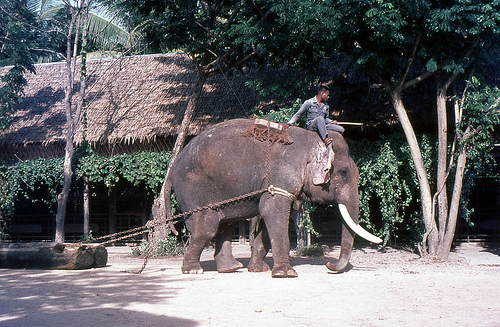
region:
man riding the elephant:
[213, 55, 407, 293]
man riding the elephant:
[247, 68, 372, 234]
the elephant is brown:
[157, 94, 369, 287]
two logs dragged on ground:
[0, 242, 107, 269]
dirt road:
[1, 255, 499, 324]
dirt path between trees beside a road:
[455, 235, 497, 264]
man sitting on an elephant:
[285, 86, 345, 143]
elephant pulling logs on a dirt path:
[0, 118, 382, 269]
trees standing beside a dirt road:
[52, 0, 97, 245]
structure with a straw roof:
[0, 48, 256, 241]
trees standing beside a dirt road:
[115, 0, 499, 261]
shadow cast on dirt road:
[1, 268, 214, 324]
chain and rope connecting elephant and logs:
[66, 185, 294, 248]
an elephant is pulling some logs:
[2, 81, 384, 280]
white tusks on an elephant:
[336, 200, 384, 245]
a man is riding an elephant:
[160, 75, 382, 275]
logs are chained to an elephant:
[6, 109, 387, 281]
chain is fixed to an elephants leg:
[161, 177, 308, 230]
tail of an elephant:
[161, 168, 180, 236]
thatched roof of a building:
[1, 52, 411, 152]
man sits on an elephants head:
[287, 80, 389, 275]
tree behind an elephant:
[160, 0, 499, 280]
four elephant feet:
[178, 225, 301, 280]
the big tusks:
[338, 199, 382, 249]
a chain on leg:
[82, 184, 294, 274]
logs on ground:
[1, 238, 108, 268]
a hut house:
[1, 53, 283, 241]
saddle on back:
[248, 114, 288, 141]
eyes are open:
[332, 167, 349, 177]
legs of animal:
[178, 197, 298, 277]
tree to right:
[224, 14, 499, 265]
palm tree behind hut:
[45, 3, 160, 48]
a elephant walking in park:
[162, 82, 382, 278]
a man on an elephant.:
[161, 81, 384, 281]